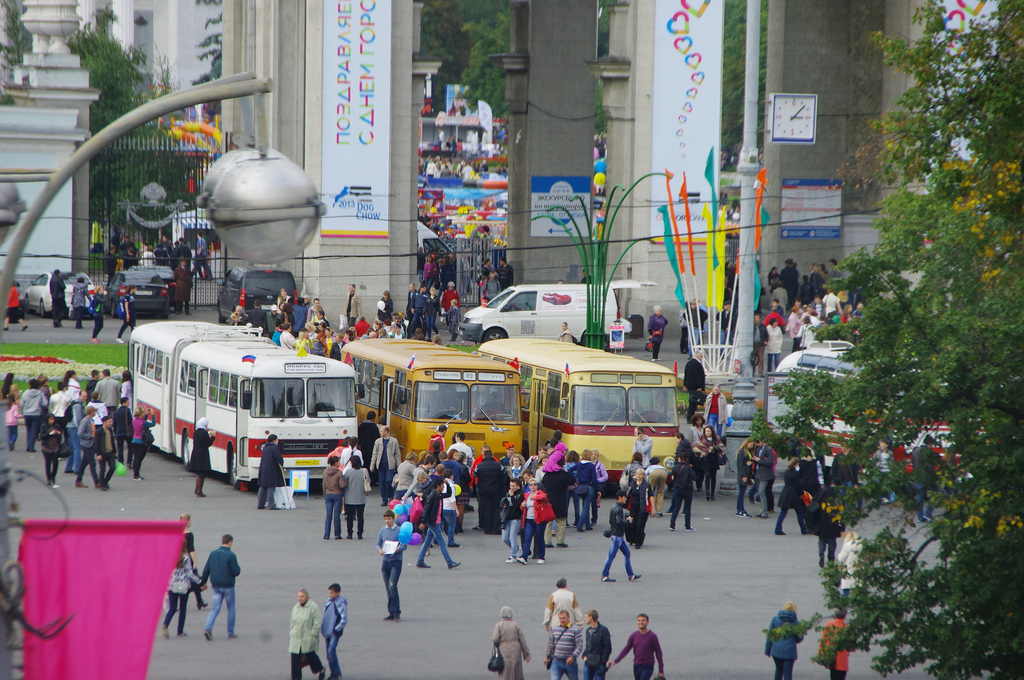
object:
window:
[306, 377, 356, 418]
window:
[250, 377, 305, 418]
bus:
[126, 320, 362, 488]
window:
[414, 381, 468, 422]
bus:
[340, 337, 521, 464]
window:
[469, 383, 519, 425]